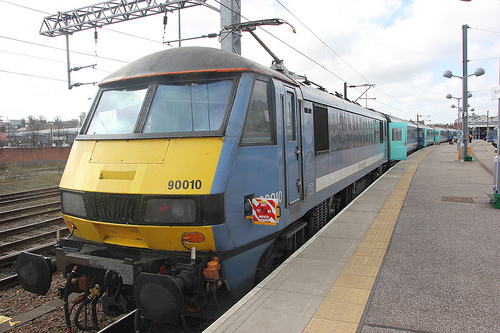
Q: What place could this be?
A: It is a train station.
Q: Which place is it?
A: It is a train station.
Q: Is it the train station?
A: Yes, it is the train station.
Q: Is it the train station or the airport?
A: It is the train station.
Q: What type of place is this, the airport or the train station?
A: It is the train station.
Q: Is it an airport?
A: No, it is a train station.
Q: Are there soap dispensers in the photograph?
A: No, there are no soap dispensers.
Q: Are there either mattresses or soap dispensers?
A: No, there are no soap dispensers or mattresses.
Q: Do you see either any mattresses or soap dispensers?
A: No, there are no soap dispensers or mattresses.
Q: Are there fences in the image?
A: No, there are no fences.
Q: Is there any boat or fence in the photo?
A: No, there are no fences or boats.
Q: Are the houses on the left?
A: Yes, the houses are on the left of the image.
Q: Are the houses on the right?
A: No, the houses are on the left of the image.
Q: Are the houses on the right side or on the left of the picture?
A: The houses are on the left of the image.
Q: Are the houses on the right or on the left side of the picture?
A: The houses are on the left of the image.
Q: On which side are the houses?
A: The houses are on the left of the image.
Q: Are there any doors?
A: Yes, there is a door.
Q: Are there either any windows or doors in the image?
A: Yes, there is a door.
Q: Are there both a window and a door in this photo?
A: Yes, there are both a door and a window.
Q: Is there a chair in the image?
A: No, there are no chairs.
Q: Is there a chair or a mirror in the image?
A: No, there are no chairs or mirrors.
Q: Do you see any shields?
A: No, there are no shields.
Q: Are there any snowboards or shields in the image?
A: No, there are no shields or snowboards.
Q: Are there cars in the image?
A: No, there are no cars.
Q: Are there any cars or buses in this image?
A: No, there are no cars or buses.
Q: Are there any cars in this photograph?
A: No, there are no cars.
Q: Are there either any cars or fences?
A: No, there are no cars or fences.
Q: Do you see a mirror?
A: No, there are no mirrors.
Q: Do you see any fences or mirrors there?
A: No, there are no mirrors or fences.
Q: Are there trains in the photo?
A: Yes, there is a train.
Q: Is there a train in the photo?
A: Yes, there is a train.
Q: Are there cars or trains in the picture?
A: Yes, there is a train.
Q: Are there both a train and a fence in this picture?
A: No, there is a train but no fences.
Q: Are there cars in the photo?
A: No, there are no cars.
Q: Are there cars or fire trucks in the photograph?
A: No, there are no cars or fire trucks.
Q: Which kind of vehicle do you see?
A: The vehicle is a train.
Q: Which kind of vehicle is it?
A: The vehicle is a train.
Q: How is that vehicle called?
A: This is a train.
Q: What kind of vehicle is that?
A: This is a train.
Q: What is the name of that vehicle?
A: This is a train.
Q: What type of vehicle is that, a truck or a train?
A: This is a train.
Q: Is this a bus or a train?
A: This is a train.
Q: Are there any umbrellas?
A: No, there are no umbrellas.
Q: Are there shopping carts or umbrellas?
A: No, there are no umbrellas or shopping carts.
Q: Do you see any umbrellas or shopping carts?
A: No, there are no umbrellas or shopping carts.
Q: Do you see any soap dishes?
A: No, there are no soap dishes.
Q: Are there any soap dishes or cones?
A: No, there are no soap dishes or cones.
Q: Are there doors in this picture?
A: Yes, there is a door.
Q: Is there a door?
A: Yes, there is a door.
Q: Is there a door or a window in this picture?
A: Yes, there is a door.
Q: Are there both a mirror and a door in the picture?
A: No, there is a door but no mirrors.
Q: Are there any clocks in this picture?
A: No, there are no clocks.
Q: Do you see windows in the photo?
A: Yes, there is a window.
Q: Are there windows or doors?
A: Yes, there is a window.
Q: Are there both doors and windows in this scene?
A: Yes, there are both a window and a door.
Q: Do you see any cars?
A: No, there are no cars.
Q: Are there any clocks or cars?
A: No, there are no cars or clocks.